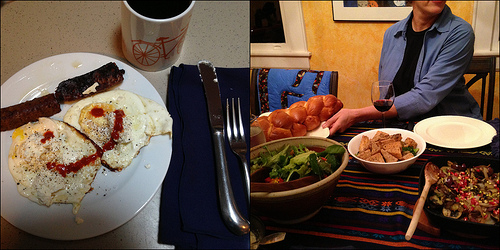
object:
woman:
[342, 0, 490, 128]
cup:
[367, 75, 399, 127]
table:
[255, 101, 499, 249]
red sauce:
[88, 103, 108, 121]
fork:
[224, 95, 257, 211]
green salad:
[251, 143, 342, 180]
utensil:
[400, 160, 441, 240]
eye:
[40, 130, 55, 145]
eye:
[89, 107, 107, 119]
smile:
[45, 109, 125, 177]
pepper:
[57, 124, 102, 147]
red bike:
[129, 24, 193, 67]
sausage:
[56, 60, 123, 103]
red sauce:
[98, 108, 128, 152]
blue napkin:
[156, 64, 252, 249]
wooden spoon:
[403, 156, 440, 241]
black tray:
[417, 155, 500, 241]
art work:
[341, 0, 412, 9]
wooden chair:
[443, 50, 500, 119]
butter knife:
[199, 59, 255, 231]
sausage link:
[56, 60, 126, 105]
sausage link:
[2, 91, 62, 131]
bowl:
[249, 134, 349, 224]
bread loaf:
[250, 92, 344, 146]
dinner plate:
[410, 113, 498, 153]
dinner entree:
[428, 161, 500, 220]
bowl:
[346, 126, 427, 175]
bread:
[366, 141, 384, 155]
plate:
[2, 48, 174, 244]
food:
[1, 60, 170, 210]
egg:
[8, 115, 102, 214]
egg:
[63, 88, 172, 170]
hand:
[322, 108, 365, 137]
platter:
[252, 104, 334, 140]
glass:
[370, 91, 397, 101]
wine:
[372, 97, 396, 114]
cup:
[116, 0, 195, 71]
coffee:
[126, 1, 193, 21]